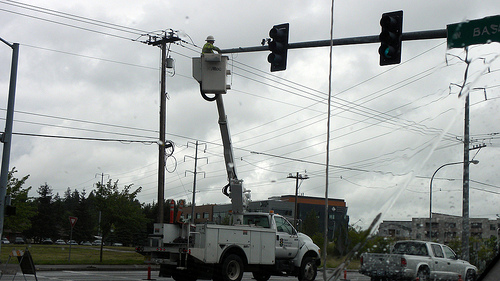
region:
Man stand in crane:
[186, 27, 236, 101]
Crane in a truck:
[191, 49, 257, 228]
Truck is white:
[137, 206, 327, 279]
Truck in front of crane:
[353, 224, 488, 278]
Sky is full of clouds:
[0, 6, 499, 208]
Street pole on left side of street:
[417, 151, 482, 233]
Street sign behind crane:
[7, 240, 44, 279]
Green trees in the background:
[10, 177, 148, 247]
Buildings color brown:
[369, 208, 499, 250]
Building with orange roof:
[284, 191, 359, 258]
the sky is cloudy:
[40, 68, 155, 125]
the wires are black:
[67, 12, 143, 43]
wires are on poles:
[83, 13, 190, 76]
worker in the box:
[197, 34, 229, 94]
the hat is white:
[203, 35, 221, 45]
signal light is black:
[252, 19, 297, 79]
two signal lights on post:
[243, 25, 455, 71]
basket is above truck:
[180, 32, 317, 270]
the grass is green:
[36, 241, 121, 279]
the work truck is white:
[153, 202, 330, 277]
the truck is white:
[147, 186, 327, 278]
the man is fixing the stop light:
[189, 30, 277, 125]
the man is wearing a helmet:
[193, 27, 219, 54]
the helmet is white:
[192, 27, 217, 55]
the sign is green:
[432, 11, 497, 60]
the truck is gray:
[355, 214, 493, 277]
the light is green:
[363, 27, 413, 84]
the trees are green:
[4, 162, 190, 259]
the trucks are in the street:
[146, 214, 491, 274]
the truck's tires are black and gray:
[205, 249, 345, 279]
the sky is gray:
[39, 48, 150, 135]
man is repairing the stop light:
[179, 24, 286, 112]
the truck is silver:
[332, 210, 456, 275]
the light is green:
[335, 28, 422, 92]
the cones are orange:
[157, 183, 189, 225]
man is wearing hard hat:
[194, 28, 229, 50]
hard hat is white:
[195, 33, 228, 49]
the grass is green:
[24, 243, 67, 264]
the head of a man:
[202, 32, 217, 45]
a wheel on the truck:
[215, 247, 249, 279]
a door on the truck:
[272, 212, 301, 260]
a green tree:
[25, 172, 65, 241]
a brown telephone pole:
[141, 26, 184, 224]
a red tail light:
[398, 251, 412, 268]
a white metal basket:
[191, 32, 233, 104]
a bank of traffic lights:
[263, 18, 291, 78]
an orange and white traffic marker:
[164, 193, 176, 225]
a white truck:
[141, 207, 331, 277]